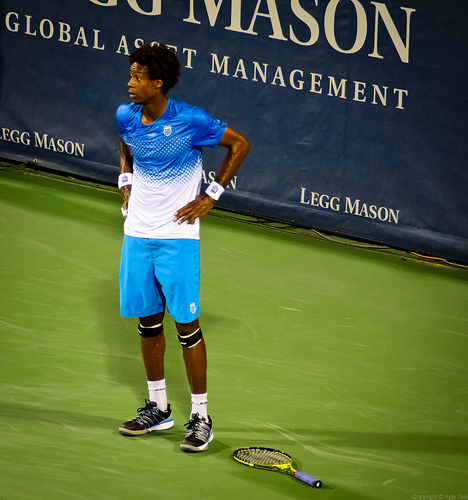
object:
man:
[115, 43, 251, 453]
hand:
[175, 194, 215, 225]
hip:
[169, 202, 207, 244]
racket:
[233, 447, 321, 489]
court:
[1, 157, 465, 498]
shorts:
[120, 234, 203, 324]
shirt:
[115, 101, 228, 241]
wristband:
[206, 181, 225, 200]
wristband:
[118, 172, 134, 189]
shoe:
[180, 413, 214, 453]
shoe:
[120, 400, 175, 436]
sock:
[147, 378, 170, 413]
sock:
[189, 392, 212, 427]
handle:
[292, 469, 323, 489]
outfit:
[116, 100, 228, 325]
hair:
[127, 43, 182, 95]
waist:
[128, 180, 201, 225]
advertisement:
[2, 0, 467, 270]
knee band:
[137, 324, 165, 338]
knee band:
[178, 328, 203, 350]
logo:
[189, 302, 198, 315]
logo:
[162, 124, 173, 137]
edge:
[1, 159, 467, 272]